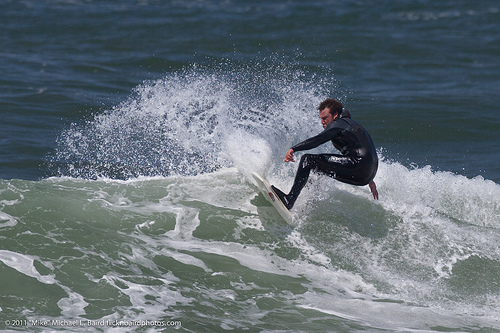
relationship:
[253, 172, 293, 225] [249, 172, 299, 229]
edge of board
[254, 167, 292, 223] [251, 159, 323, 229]
edge of board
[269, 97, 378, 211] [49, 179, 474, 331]
man over water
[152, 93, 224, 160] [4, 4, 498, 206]
water drops in air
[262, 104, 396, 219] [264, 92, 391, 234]
wetsuit on man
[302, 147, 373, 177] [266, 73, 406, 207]
reflection on wetsuit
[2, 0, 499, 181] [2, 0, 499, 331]
ripples on surface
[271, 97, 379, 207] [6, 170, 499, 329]
man surfing wave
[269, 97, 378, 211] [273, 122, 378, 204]
man wearing wetsuit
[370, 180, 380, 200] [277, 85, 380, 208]
hand behind body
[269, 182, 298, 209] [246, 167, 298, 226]
feet on board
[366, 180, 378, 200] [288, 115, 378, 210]
hand wears wetsuit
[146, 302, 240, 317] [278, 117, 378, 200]
part of a costume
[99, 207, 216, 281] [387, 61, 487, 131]
part of a water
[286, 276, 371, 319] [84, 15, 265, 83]
part of a water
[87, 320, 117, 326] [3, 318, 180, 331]
part of a graphic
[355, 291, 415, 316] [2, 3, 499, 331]
part of a water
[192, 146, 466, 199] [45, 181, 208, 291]
foam in water